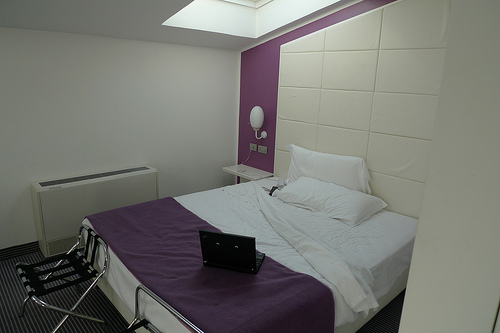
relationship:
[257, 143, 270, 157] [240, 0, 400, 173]
electrical plate mounted on wall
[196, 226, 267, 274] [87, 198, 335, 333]
computer on top of blanket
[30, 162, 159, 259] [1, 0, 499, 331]
heater inside bedroom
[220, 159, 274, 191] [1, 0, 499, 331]
table inside bedroom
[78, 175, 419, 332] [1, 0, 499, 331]
bed in middle of bedroom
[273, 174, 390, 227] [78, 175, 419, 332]
pillow on top of bed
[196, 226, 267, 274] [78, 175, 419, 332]
computer on top of bed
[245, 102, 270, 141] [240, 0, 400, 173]
lamp attached to wall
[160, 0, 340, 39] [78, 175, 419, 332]
skylight window hanging above bed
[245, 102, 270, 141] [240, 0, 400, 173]
lamp hanging on wall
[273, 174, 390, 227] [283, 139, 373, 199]
pillow leaning on other pillow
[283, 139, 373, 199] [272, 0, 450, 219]
pillow leaning on wall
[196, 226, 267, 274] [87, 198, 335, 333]
computer sitting on top of blanket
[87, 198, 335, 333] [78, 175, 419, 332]
blanket laid on bed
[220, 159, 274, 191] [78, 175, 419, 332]
table next to bed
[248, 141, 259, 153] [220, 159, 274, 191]
electrical outlet mounted above table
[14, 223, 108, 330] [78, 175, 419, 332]
chair in front of bed